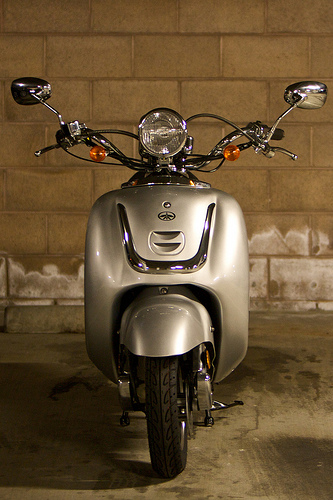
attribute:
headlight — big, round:
[137, 107, 189, 157]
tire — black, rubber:
[139, 355, 195, 488]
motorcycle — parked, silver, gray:
[6, 75, 330, 478]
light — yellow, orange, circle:
[221, 143, 242, 162]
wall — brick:
[2, 1, 330, 308]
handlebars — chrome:
[29, 117, 301, 166]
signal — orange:
[84, 141, 117, 166]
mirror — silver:
[282, 82, 329, 114]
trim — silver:
[74, 176, 252, 405]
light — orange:
[91, 144, 108, 163]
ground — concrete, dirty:
[0, 304, 330, 499]